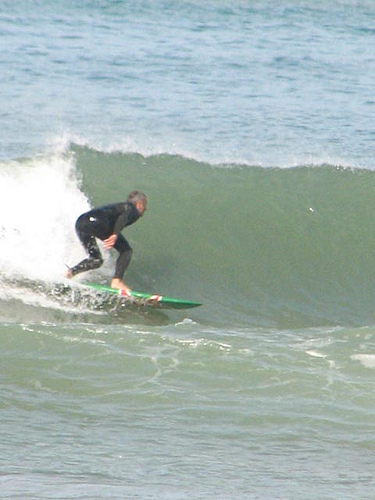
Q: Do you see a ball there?
A: No, there are no balls.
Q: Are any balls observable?
A: No, there are no balls.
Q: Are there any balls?
A: No, there are no balls.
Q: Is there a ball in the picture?
A: No, there are no balls.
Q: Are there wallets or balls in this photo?
A: No, there are no balls or wallets.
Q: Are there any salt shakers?
A: No, there are no salt shakers.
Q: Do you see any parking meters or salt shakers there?
A: No, there are no salt shakers or parking meters.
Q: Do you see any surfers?
A: Yes, there is a surfer.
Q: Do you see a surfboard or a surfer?
A: Yes, there is a surfer.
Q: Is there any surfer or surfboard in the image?
A: Yes, there is a surfer.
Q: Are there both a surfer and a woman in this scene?
A: No, there is a surfer but no women.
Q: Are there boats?
A: No, there are no boats.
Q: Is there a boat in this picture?
A: No, there are no boats.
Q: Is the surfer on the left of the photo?
A: Yes, the surfer is on the left of the image.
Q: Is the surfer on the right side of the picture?
A: No, the surfer is on the left of the image.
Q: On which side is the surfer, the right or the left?
A: The surfer is on the left of the image.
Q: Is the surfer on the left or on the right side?
A: The surfer is on the left of the image.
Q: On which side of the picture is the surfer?
A: The surfer is on the left of the image.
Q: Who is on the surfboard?
A: The surfer is on the surfboard.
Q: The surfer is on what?
A: The surfer is on the surfboard.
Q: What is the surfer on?
A: The surfer is on the surfboard.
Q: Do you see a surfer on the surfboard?
A: Yes, there is a surfer on the surfboard.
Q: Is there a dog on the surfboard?
A: No, there is a surfer on the surfboard.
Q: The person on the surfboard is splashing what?
A: The surfer is splashing the water.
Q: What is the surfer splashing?
A: The surfer is splashing the water.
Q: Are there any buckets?
A: No, there are no buckets.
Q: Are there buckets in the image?
A: No, there are no buckets.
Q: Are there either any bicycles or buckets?
A: No, there are no buckets or bicycles.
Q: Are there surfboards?
A: Yes, there is a surfboard.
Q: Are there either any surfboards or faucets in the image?
A: Yes, there is a surfboard.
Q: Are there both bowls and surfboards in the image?
A: No, there is a surfboard but no bowls.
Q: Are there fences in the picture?
A: No, there are no fences.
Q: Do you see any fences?
A: No, there are no fences.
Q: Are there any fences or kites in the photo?
A: No, there are no fences or kites.